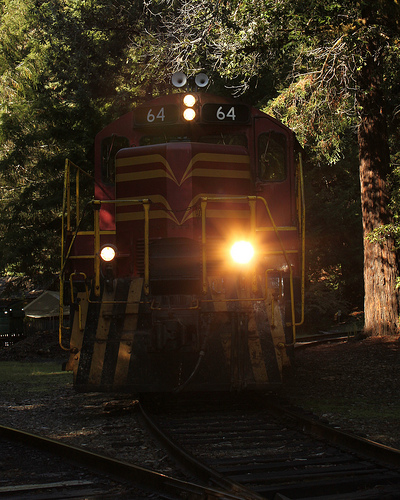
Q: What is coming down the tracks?
A: Locomotive.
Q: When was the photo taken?
A: Evening.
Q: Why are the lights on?
A: Required by law.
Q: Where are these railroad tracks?
A: Forest.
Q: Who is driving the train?
A: Engineer.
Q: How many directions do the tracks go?
A: 2.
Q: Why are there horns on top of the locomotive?
A: For signalling.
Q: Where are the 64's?
A: On the front of the locomotive.